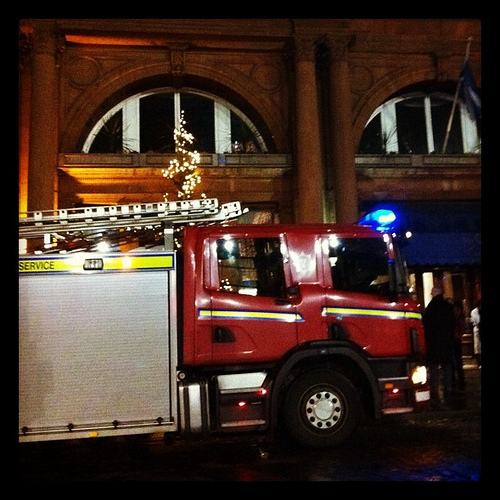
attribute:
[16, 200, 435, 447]
truck — red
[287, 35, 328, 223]
column — stone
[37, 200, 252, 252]
ladder — silver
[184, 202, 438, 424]
truck — red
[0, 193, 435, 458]
firetruck — red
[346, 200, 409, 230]
light — blue